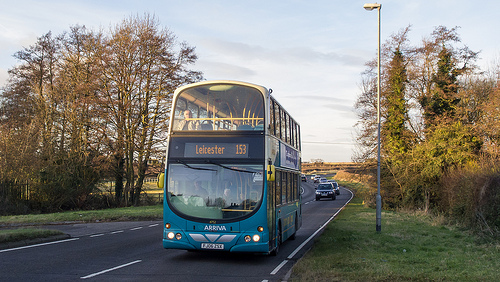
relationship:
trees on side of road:
[5, 23, 494, 228] [0, 185, 350, 277]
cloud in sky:
[193, 22, 314, 93] [248, 20, 289, 52]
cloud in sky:
[306, 77, 348, 130] [248, 20, 289, 52]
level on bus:
[158, 61, 302, 159] [165, 83, 305, 257]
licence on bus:
[201, 242, 223, 249] [165, 83, 305, 257]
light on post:
[358, 0, 389, 14] [374, 5, 382, 234]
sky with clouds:
[0, 1, 499, 163] [2, 0, 492, 150]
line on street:
[81, 255, 142, 280] [2, 175, 352, 279]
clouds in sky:
[317, 103, 370, 121] [0, 1, 499, 163]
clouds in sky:
[296, 38, 371, 118] [23, 10, 488, 153]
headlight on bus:
[166, 231, 174, 238] [165, 83, 305, 257]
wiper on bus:
[180, 157, 218, 172] [165, 83, 305, 257]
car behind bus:
[312, 182, 334, 200] [155, 72, 308, 262]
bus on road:
[143, 77, 300, 247] [0, 173, 350, 281]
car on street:
[312, 182, 334, 200] [2, 175, 352, 279]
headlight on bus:
[166, 231, 174, 238] [155, 80, 302, 255]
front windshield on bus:
[165, 161, 264, 220] [165, 83, 305, 257]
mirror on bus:
[264, 152, 274, 178] [165, 83, 305, 257]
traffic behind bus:
[300, 166, 340, 203] [165, 83, 305, 257]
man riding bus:
[175, 105, 196, 137] [165, 83, 305, 257]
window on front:
[168, 161, 270, 223] [172, 91, 264, 235]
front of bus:
[172, 91, 264, 235] [165, 83, 305, 257]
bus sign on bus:
[190, 138, 248, 160] [165, 83, 305, 257]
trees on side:
[351, 21, 419, 210] [320, 187, 342, 247]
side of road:
[320, 187, 342, 247] [111, 169, 351, 279]